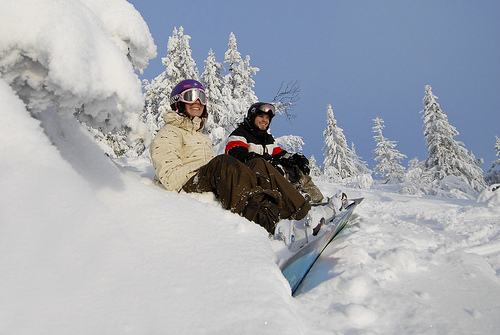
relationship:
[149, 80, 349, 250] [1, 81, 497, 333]
couple sitting in snow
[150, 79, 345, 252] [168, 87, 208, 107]
woman wearing goggles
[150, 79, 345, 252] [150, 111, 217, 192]
woman wearing a coat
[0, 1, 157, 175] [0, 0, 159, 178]
tree covered with snow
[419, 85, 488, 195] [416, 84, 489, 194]
tree covered with snow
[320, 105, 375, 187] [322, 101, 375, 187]
tree covered with snow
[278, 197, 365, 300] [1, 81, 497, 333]
snowboard on snow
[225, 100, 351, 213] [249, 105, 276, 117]
man wearing goggles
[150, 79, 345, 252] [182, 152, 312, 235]
woman wearing pants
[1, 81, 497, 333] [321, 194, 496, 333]
snow has tracks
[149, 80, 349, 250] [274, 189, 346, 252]
couple wearing snowboots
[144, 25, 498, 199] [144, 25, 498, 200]
trees are covered with snow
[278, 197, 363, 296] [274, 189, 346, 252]
snowboard are attached to snowboots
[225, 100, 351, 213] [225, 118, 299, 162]
man wearing a coat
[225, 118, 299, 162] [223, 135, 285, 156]
coat has red and white stripes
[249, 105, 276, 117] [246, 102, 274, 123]
goggles are on helmet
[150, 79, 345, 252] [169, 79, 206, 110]
woman wearing helmet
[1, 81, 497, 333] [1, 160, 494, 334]
snow on ground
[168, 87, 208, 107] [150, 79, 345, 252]
goggles are worn by woman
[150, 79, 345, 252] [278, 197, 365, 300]
woman wearing a snowboard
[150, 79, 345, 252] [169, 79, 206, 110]
woman wearing a helmet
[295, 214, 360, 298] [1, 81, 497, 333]
shadow in snow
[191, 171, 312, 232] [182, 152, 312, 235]
snow on pants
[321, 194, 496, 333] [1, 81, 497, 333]
tracks in snow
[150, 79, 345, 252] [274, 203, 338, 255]
woman wearing snowboots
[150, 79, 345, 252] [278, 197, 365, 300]
woman wearing snowboard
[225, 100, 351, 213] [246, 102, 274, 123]
man wearing a helmet